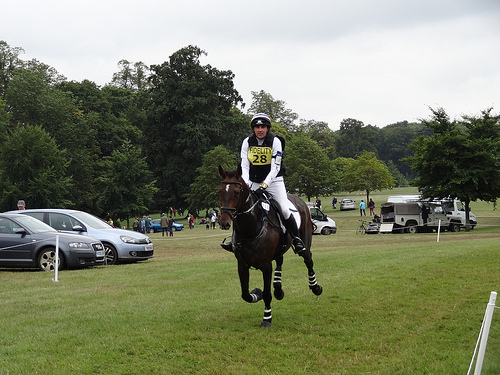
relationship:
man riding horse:
[240, 112, 304, 251] [216, 163, 323, 328]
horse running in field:
[216, 163, 323, 328] [1, 185, 499, 375]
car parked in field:
[1, 213, 106, 271] [1, 185, 499, 375]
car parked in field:
[17, 207, 156, 268] [1, 185, 499, 375]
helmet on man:
[249, 111, 272, 129] [240, 112, 304, 251]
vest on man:
[247, 133, 287, 183] [240, 112, 304, 251]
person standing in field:
[357, 198, 368, 219] [1, 185, 499, 375]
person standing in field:
[365, 199, 378, 216] [1, 185, 499, 375]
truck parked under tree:
[377, 204, 463, 238] [412, 109, 500, 232]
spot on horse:
[225, 180, 230, 192] [216, 163, 323, 328]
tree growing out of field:
[412, 109, 500, 232] [1, 185, 499, 375]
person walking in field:
[357, 198, 368, 219] [1, 185, 499, 375]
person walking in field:
[365, 199, 378, 216] [1, 185, 499, 375]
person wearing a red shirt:
[187, 213, 196, 229] [190, 214, 195, 222]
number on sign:
[249, 155, 266, 164] [249, 146, 275, 167]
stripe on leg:
[263, 307, 274, 314] [258, 260, 274, 328]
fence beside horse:
[467, 302, 487, 375] [216, 163, 323, 328]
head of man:
[249, 112, 270, 139] [240, 112, 304, 251]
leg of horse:
[258, 260, 274, 328] [216, 163, 323, 328]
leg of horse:
[301, 248, 322, 298] [216, 163, 323, 328]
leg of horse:
[238, 256, 265, 305] [216, 163, 323, 328]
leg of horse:
[269, 254, 286, 302] [216, 163, 323, 328]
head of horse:
[214, 163, 243, 229] [216, 163, 323, 328]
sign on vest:
[249, 146, 275, 167] [247, 133, 287, 183]